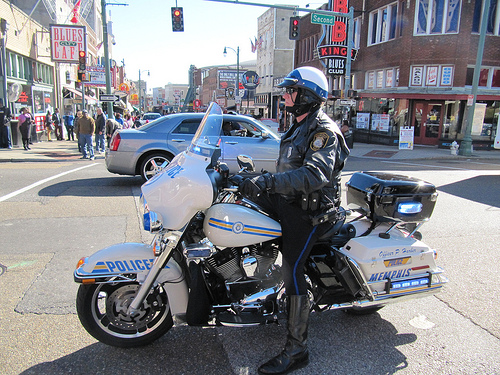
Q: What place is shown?
A: It is a street.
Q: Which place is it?
A: It is a street.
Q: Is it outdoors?
A: Yes, it is outdoors.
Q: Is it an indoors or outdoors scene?
A: It is outdoors.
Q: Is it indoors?
A: No, it is outdoors.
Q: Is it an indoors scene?
A: No, it is outdoors.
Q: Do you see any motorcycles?
A: Yes, there is a motorcycle.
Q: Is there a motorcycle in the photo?
A: Yes, there is a motorcycle.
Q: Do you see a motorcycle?
A: Yes, there is a motorcycle.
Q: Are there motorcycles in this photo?
A: Yes, there is a motorcycle.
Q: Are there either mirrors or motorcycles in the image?
A: Yes, there is a motorcycle.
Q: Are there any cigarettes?
A: No, there are no cigarettes.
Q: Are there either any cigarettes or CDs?
A: No, there are no cigarettes or cds.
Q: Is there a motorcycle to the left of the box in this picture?
A: Yes, there is a motorcycle to the left of the box.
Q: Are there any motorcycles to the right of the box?
A: No, the motorcycle is to the left of the box.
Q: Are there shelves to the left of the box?
A: No, there is a motorcycle to the left of the box.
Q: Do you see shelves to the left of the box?
A: No, there is a motorcycle to the left of the box.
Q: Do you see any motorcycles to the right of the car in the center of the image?
A: Yes, there is a motorcycle to the right of the car.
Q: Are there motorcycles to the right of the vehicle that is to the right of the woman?
A: Yes, there is a motorcycle to the right of the car.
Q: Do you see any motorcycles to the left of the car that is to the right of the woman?
A: No, the motorcycle is to the right of the car.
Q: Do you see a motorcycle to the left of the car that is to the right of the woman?
A: No, the motorcycle is to the right of the car.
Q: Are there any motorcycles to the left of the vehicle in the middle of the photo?
A: No, the motorcycle is to the right of the car.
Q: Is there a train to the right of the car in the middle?
A: No, there is a motorcycle to the right of the car.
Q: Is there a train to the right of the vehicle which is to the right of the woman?
A: No, there is a motorcycle to the right of the car.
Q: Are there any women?
A: Yes, there is a woman.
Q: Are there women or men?
A: Yes, there is a woman.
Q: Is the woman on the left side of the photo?
A: Yes, the woman is on the left of the image.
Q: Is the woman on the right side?
A: No, the woman is on the left of the image.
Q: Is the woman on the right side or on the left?
A: The woman is on the left of the image.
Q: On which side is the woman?
A: The woman is on the left of the image.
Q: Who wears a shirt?
A: The woman wears a shirt.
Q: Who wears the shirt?
A: The woman wears a shirt.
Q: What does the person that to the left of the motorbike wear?
A: The woman wears a shirt.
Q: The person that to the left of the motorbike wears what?
A: The woman wears a shirt.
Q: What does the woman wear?
A: The woman wears a shirt.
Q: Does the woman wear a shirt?
A: Yes, the woman wears a shirt.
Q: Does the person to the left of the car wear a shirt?
A: Yes, the woman wears a shirt.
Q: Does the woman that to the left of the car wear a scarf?
A: No, the woman wears a shirt.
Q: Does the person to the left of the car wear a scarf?
A: No, the woman wears a shirt.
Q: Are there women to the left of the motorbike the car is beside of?
A: Yes, there is a woman to the left of the motorcycle.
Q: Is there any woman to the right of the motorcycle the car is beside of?
A: No, the woman is to the left of the motorcycle.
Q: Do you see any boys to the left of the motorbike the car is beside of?
A: No, there is a woman to the left of the motorbike.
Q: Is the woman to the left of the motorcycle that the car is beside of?
A: Yes, the woman is to the left of the motorcycle.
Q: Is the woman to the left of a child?
A: No, the woman is to the left of the motorcycle.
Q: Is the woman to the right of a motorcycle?
A: No, the woman is to the left of a motorcycle.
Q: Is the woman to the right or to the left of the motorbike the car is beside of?
A: The woman is to the left of the motorcycle.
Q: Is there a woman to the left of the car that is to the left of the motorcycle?
A: Yes, there is a woman to the left of the car.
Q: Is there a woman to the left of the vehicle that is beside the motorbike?
A: Yes, there is a woman to the left of the car.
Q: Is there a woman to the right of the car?
A: No, the woman is to the left of the car.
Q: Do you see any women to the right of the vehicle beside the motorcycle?
A: No, the woman is to the left of the car.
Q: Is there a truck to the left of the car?
A: No, there is a woman to the left of the car.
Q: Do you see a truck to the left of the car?
A: No, there is a woman to the left of the car.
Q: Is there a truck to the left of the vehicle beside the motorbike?
A: No, there is a woman to the left of the car.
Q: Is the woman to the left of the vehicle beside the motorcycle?
A: Yes, the woman is to the left of the car.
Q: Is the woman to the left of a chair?
A: No, the woman is to the left of the car.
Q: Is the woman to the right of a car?
A: No, the woman is to the left of a car.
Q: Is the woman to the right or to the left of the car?
A: The woman is to the left of the car.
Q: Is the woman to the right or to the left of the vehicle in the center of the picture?
A: The woman is to the left of the car.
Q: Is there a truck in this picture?
A: No, there are no trucks.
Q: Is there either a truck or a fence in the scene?
A: No, there are no trucks or fences.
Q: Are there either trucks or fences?
A: No, there are no trucks or fences.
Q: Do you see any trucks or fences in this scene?
A: No, there are no trucks or fences.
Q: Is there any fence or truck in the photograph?
A: No, there are no trucks or fences.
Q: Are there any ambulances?
A: No, there are no ambulances.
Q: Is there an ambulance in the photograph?
A: No, there are no ambulances.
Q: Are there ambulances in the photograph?
A: No, there are no ambulances.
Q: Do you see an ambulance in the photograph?
A: No, there are no ambulances.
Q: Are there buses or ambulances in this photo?
A: No, there are no ambulances or buses.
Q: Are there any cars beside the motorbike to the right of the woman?
A: Yes, there is a car beside the motorcycle.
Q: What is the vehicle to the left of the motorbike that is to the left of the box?
A: The vehicle is a car.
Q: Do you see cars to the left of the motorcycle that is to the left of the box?
A: Yes, there is a car to the left of the motorcycle.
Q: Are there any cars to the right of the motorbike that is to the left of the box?
A: No, the car is to the left of the motorbike.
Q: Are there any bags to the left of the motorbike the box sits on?
A: No, there is a car to the left of the motorcycle.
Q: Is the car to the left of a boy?
A: No, the car is to the left of the motorcycle.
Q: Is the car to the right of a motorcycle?
A: No, the car is to the left of a motorcycle.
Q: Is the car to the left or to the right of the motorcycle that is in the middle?
A: The car is to the left of the motorcycle.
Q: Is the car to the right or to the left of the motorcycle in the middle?
A: The car is to the left of the motorcycle.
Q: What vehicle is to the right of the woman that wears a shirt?
A: The vehicle is a car.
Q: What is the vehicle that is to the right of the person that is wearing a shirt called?
A: The vehicle is a car.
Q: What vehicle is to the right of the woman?
A: The vehicle is a car.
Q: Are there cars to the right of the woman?
A: Yes, there is a car to the right of the woman.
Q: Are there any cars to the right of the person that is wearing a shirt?
A: Yes, there is a car to the right of the woman.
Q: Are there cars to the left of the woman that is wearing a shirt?
A: No, the car is to the right of the woman.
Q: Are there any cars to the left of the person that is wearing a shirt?
A: No, the car is to the right of the woman.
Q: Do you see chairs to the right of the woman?
A: No, there is a car to the right of the woman.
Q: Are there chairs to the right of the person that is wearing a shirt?
A: No, there is a car to the right of the woman.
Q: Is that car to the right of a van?
A: No, the car is to the right of the woman.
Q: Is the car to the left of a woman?
A: No, the car is to the right of a woman.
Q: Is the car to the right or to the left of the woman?
A: The car is to the right of the woman.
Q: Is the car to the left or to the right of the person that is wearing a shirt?
A: The car is to the right of the woman.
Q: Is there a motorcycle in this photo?
A: Yes, there is a motorcycle.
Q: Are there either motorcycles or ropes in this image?
A: Yes, there is a motorcycle.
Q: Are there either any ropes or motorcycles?
A: Yes, there is a motorcycle.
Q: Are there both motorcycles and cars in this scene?
A: Yes, there are both a motorcycle and a car.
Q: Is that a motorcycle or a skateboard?
A: That is a motorcycle.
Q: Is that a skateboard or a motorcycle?
A: That is a motorcycle.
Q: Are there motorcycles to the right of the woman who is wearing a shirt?
A: Yes, there is a motorcycle to the right of the woman.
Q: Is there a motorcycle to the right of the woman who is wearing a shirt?
A: Yes, there is a motorcycle to the right of the woman.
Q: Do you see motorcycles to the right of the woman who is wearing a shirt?
A: Yes, there is a motorcycle to the right of the woman.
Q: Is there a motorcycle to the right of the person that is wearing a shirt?
A: Yes, there is a motorcycle to the right of the woman.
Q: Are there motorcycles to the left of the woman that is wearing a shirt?
A: No, the motorcycle is to the right of the woman.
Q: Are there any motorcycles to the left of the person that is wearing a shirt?
A: No, the motorcycle is to the right of the woman.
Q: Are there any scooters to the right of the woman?
A: No, there is a motorcycle to the right of the woman.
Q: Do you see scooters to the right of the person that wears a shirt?
A: No, there is a motorcycle to the right of the woman.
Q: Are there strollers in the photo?
A: No, there are no strollers.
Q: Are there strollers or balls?
A: No, there are no strollers or balls.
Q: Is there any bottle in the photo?
A: No, there are no bottles.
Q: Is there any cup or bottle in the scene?
A: No, there are no bottles or cups.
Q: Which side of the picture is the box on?
A: The box is on the right of the image.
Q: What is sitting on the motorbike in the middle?
A: The box is sitting on the motorcycle.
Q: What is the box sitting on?
A: The box is sitting on the motorcycle.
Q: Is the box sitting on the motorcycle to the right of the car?
A: Yes, the box is sitting on the motorbike.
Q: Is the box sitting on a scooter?
A: No, the box is sitting on the motorbike.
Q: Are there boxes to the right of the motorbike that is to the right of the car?
A: Yes, there is a box to the right of the motorbike.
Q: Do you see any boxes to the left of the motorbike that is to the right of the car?
A: No, the box is to the right of the motorcycle.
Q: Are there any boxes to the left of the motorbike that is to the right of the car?
A: No, the box is to the right of the motorcycle.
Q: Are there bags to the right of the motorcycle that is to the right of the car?
A: No, there is a box to the right of the motorbike.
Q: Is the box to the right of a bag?
A: No, the box is to the right of the motorbike.